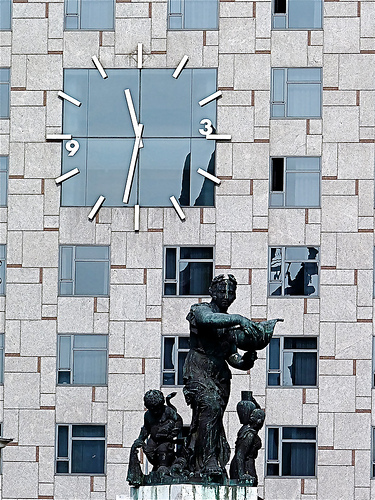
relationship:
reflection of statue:
[172, 141, 219, 210] [102, 257, 284, 487]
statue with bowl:
[183, 273, 266, 481] [246, 310, 294, 362]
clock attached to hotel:
[42, 38, 235, 237] [3, 1, 372, 499]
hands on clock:
[114, 87, 143, 193] [42, 38, 235, 237]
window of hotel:
[253, 61, 337, 123] [3, 1, 372, 499]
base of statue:
[128, 477, 264, 500] [102, 257, 284, 487]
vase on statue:
[161, 453, 250, 465] [102, 257, 284, 487]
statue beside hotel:
[102, 257, 284, 487] [3, 1, 372, 499]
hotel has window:
[3, 1, 372, 499] [253, 61, 337, 123]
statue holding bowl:
[183, 273, 266, 481] [246, 310, 294, 362]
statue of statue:
[102, 257, 284, 487] [183, 273, 266, 481]